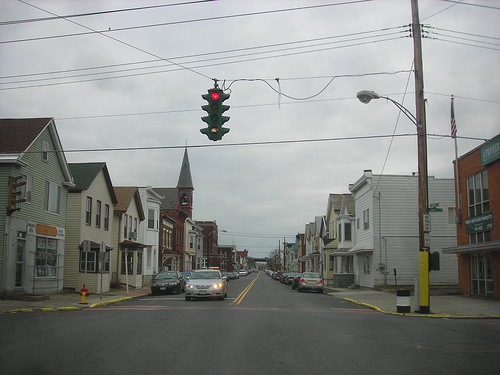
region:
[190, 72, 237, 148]
traffic light hung on a string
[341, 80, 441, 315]
a light on a pole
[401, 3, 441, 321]
a pole on the corner of a street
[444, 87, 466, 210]
an American flag on a building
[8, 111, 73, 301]
a green home color green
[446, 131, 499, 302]
a building that is red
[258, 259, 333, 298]
parked cars on a side street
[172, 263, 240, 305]
a car is stopped in a corner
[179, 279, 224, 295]
headlights are turn on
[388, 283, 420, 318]
a white and black trash can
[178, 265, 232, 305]
car on a street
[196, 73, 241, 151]
traffic signal on a wire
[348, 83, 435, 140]
streetlight on a pole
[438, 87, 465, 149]
flag on a pole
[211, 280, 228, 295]
headlight on a vehicle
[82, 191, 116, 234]
windows on a building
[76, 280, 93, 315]
fire hydrant on a sidewalk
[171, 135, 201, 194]
steeple on a building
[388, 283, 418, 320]
black and white barrel on a sidewalk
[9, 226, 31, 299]
door on a building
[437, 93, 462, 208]
An American flag.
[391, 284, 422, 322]
A trashcan on the corner of a sidewalk.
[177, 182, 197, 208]
A bell in a belltower.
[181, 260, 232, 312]
An oncoming silver car, with headlights on.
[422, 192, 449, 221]
A street sign in green.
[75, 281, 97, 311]
A yellow and red fire hydrant.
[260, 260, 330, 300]
Cars parked on the side on the road.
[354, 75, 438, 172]
A street light on a pole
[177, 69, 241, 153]
A stoplight on red, hanging above the street.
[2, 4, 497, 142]
Power lines above the street.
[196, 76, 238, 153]
Traffic light at an intersection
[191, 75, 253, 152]
Traffic light is red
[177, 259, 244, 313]
Silver car has lights on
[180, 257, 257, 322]
Silver car stopped at intersection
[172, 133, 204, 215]
Church has a pointed spire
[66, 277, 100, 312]
Fire hydrant on sidewalk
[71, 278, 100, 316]
Fire hydrant has a red top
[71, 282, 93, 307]
Base of fire hydrant is red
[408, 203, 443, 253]
Signs posted on a light pole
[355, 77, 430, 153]
Light on pole is off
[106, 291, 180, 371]
The street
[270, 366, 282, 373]
The street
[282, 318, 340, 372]
The street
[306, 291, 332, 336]
The street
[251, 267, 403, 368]
The street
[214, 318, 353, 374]
The street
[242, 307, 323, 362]
The street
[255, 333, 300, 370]
The street